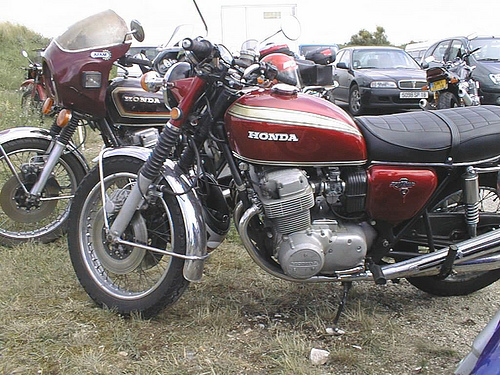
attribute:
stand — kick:
[324, 282, 359, 334]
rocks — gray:
[306, 325, 374, 364]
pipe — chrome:
[364, 225, 499, 276]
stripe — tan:
[230, 95, 360, 139]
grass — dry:
[4, 222, 498, 372]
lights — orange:
[37, 95, 77, 130]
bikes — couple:
[4, 6, 499, 337]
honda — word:
[238, 119, 317, 155]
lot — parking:
[3, 9, 497, 329]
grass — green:
[4, 17, 488, 373]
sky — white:
[7, 3, 498, 56]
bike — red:
[64, 37, 496, 326]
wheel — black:
[63, 149, 193, 327]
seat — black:
[346, 90, 496, 164]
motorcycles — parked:
[1, 6, 499, 333]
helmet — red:
[254, 45, 340, 101]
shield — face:
[264, 58, 302, 88]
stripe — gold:
[229, 100, 357, 134]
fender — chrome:
[83, 136, 216, 291]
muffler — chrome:
[334, 223, 500, 293]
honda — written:
[241, 122, 305, 152]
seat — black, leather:
[345, 97, 498, 182]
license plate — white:
[395, 88, 435, 105]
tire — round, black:
[59, 153, 194, 321]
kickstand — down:
[328, 272, 358, 336]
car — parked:
[314, 40, 442, 118]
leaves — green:
[344, 26, 393, 48]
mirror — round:
[118, 13, 155, 58]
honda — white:
[247, 130, 299, 142]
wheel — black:
[63, 143, 212, 330]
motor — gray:
[250, 163, 380, 281]